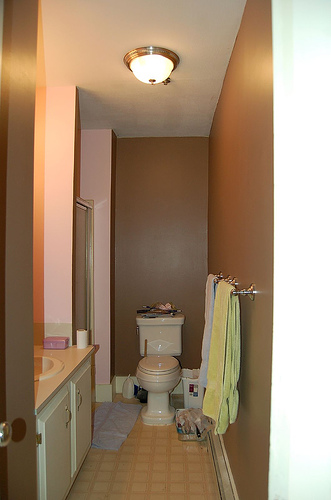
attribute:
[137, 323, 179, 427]
toilet — porcelain, white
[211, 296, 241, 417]
towel — yellow, white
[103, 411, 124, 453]
towel — purple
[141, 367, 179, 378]
seat — white, porcelain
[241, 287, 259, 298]
towel rack — silver, metal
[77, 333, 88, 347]
roll — white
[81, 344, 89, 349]
toilet paper — white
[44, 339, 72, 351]
container — pink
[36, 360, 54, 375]
sink — round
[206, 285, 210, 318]
towel — white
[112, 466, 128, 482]
pattern — square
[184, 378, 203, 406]
trashcan — white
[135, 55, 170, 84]
light — on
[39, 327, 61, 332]
trim — green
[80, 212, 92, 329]
shower — glass